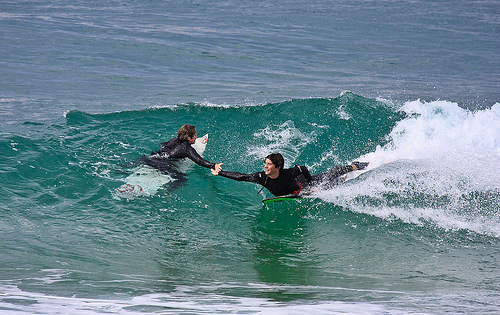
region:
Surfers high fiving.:
[148, 73, 330, 207]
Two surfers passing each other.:
[90, 125, 391, 210]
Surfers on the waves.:
[108, 105, 399, 282]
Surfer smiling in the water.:
[151, 109, 397, 229]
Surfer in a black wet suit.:
[237, 142, 354, 204]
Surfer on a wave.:
[118, 92, 426, 278]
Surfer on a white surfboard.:
[90, 115, 215, 186]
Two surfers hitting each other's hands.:
[118, 120, 386, 220]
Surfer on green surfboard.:
[238, 146, 353, 236]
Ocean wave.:
[102, 80, 377, 232]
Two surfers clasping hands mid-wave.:
[109, 111, 381, 208]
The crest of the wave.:
[60, 83, 390, 123]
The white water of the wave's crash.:
[370, 94, 497, 226]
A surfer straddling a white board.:
[108, 114, 223, 201]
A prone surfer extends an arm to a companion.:
[211, 146, 381, 212]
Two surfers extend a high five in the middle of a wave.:
[101, 111, 386, 217]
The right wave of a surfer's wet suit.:
[160, 165, 200, 198]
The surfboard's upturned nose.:
[197, 126, 219, 154]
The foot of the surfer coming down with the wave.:
[348, 157, 376, 173]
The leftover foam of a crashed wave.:
[2, 259, 400, 314]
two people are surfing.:
[140, 112, 335, 209]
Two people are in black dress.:
[145, 123, 301, 199]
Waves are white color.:
[393, 93, 495, 179]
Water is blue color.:
[50, 20, 180, 67]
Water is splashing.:
[360, 107, 460, 197]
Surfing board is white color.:
[115, 156, 171, 197]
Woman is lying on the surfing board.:
[147, 125, 193, 175]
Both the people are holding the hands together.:
[200, 156, 233, 179]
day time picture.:
[22, 32, 467, 273]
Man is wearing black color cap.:
[258, 150, 296, 170]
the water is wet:
[87, 207, 261, 304]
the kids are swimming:
[137, 107, 363, 222]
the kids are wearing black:
[142, 112, 333, 213]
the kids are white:
[127, 113, 328, 224]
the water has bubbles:
[390, 114, 498, 236]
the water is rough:
[62, 236, 220, 296]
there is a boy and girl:
[132, 105, 337, 216]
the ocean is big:
[75, 20, 237, 84]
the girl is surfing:
[103, 103, 216, 211]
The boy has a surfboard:
[220, 147, 397, 219]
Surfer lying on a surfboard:
[211, 143, 371, 217]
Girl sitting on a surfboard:
[129, 114, 220, 191]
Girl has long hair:
[133, 119, 217, 196]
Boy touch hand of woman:
[127, 116, 376, 217]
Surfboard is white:
[116, 133, 214, 214]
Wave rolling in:
[44, 87, 498, 270]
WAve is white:
[387, 101, 498, 202]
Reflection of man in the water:
[234, 201, 327, 291]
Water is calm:
[13, 8, 497, 88]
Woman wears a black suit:
[133, 116, 225, 200]